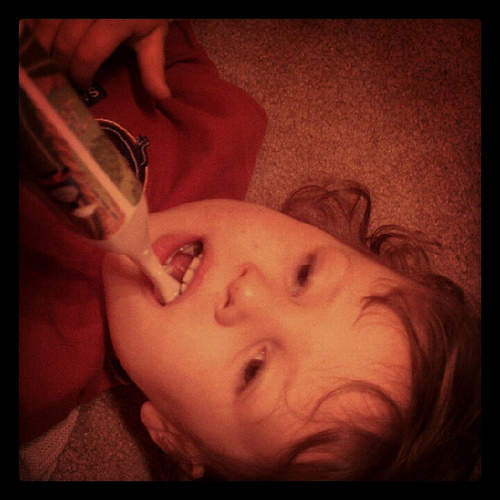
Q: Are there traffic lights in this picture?
A: No, there are no traffic lights.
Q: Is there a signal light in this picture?
A: No, there are no traffic lights.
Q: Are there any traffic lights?
A: No, there are no traffic lights.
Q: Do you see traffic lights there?
A: No, there are no traffic lights.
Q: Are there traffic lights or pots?
A: No, there are no traffic lights or pots.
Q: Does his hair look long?
A: Yes, the hair is long.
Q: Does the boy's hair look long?
A: Yes, the hair is long.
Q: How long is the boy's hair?
A: The hair is long.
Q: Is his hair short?
A: No, the hair is long.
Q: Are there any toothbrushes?
A: Yes, there is a toothbrush.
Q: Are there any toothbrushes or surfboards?
A: Yes, there is a toothbrush.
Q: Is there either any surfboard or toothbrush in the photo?
A: Yes, there is a toothbrush.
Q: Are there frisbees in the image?
A: No, there are no frisbees.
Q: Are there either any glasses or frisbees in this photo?
A: No, there are no frisbees or glasses.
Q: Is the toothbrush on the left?
A: Yes, the toothbrush is on the left of the image.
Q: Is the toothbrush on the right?
A: No, the toothbrush is on the left of the image.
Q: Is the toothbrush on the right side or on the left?
A: The toothbrush is on the left of the image.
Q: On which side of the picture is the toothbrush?
A: The toothbrush is on the left of the image.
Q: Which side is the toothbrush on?
A: The toothbrush is on the left of the image.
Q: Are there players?
A: No, there are no players.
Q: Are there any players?
A: No, there are no players.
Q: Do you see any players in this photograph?
A: No, there are no players.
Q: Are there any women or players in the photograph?
A: No, there are no players or women.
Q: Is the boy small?
A: Yes, the boy is small.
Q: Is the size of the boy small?
A: Yes, the boy is small.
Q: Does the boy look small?
A: Yes, the boy is small.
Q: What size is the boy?
A: The boy is small.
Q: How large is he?
A: The boy is small.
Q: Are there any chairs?
A: No, there are no chairs.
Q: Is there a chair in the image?
A: No, there are no chairs.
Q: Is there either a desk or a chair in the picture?
A: No, there are no chairs or desks.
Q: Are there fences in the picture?
A: No, there are no fences.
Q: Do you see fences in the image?
A: No, there are no fences.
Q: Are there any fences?
A: No, there are no fences.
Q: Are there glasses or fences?
A: No, there are no fences or glasses.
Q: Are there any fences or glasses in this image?
A: No, there are no fences or glasses.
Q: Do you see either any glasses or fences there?
A: No, there are no fences or glasses.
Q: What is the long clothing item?
A: The clothing item is a shirt.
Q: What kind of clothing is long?
A: The clothing is a shirt.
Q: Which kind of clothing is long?
A: The clothing is a shirt.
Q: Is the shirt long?
A: Yes, the shirt is long.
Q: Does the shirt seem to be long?
A: Yes, the shirt is long.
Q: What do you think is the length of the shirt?
A: The shirt is long.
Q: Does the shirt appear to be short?
A: No, the shirt is long.